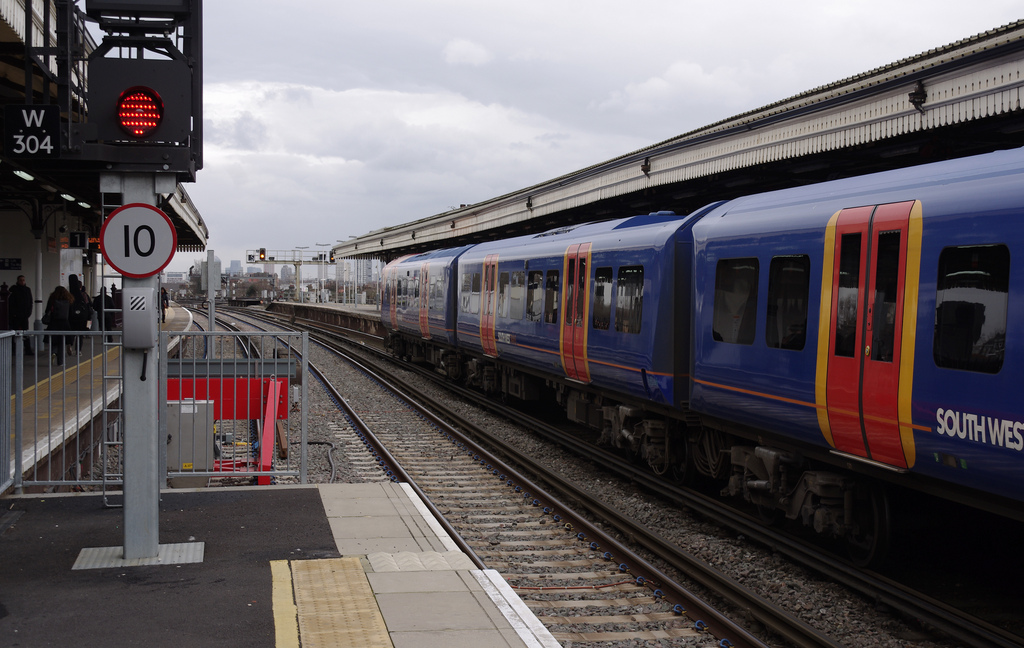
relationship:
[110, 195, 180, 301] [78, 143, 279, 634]
numbers on sign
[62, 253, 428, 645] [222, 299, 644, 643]
platform next to tracks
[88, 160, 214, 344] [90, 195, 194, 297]
sign with number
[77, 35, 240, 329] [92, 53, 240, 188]
sign with light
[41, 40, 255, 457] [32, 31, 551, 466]
sign with light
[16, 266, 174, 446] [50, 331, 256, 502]
people on platform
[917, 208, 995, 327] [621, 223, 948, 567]
window on train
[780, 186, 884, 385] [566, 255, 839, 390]
window on train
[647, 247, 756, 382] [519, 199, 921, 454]
window on train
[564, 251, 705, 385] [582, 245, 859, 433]
window on train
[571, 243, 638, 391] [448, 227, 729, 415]
window on train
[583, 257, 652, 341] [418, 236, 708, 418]
window on train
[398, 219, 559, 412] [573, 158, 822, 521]
window on train